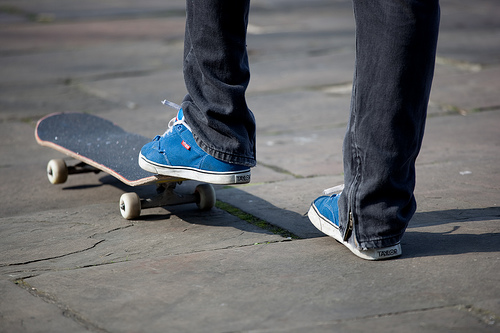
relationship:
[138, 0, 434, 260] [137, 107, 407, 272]
person wearing kicks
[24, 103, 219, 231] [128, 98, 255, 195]
skateboard under shoe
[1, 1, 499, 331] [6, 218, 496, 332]
ground made of stone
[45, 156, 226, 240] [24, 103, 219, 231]
wheels are on skateboard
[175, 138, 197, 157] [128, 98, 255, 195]
tag on shoe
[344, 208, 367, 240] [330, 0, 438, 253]
zipper on jean leg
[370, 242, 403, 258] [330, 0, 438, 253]
taylor on jean leg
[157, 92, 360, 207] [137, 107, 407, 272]
laces are on kicks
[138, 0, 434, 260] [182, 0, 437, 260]
person wearing jeans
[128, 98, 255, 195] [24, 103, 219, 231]
shoe on skateboard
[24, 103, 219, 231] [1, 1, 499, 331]
skateboard on ground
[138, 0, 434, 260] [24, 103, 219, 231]
person on skateboard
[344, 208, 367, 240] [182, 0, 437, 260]
zipper on jeans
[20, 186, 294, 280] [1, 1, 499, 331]
cracks are in ground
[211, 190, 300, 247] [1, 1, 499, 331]
grass on ground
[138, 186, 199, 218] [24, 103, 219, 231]
axel on skateboard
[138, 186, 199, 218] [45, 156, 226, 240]
axel attached to wheels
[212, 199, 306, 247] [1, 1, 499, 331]
gap in ground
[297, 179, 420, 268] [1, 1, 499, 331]
shoe on ground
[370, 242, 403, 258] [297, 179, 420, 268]
taylor on shoe